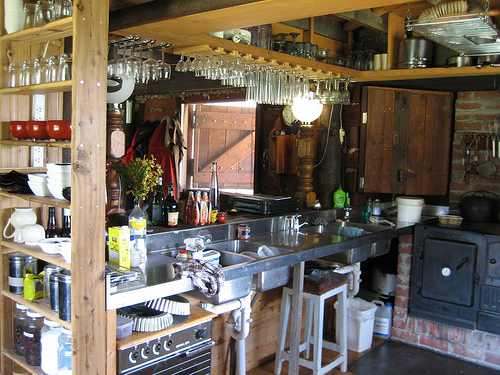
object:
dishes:
[44, 119, 73, 138]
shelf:
[0, 138, 72, 147]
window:
[184, 98, 257, 196]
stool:
[273, 271, 351, 374]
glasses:
[158, 41, 174, 79]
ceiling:
[108, 0, 407, 52]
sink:
[327, 220, 394, 234]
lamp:
[290, 98, 325, 209]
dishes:
[26, 180, 54, 197]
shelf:
[0, 189, 71, 209]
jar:
[20, 309, 45, 365]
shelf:
[1, 348, 42, 375]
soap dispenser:
[363, 196, 372, 224]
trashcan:
[333, 296, 378, 353]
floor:
[252, 321, 499, 374]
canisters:
[7, 250, 39, 295]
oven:
[405, 222, 499, 335]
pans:
[140, 293, 191, 316]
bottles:
[160, 182, 182, 228]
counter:
[129, 198, 147, 233]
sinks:
[207, 238, 302, 257]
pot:
[457, 189, 499, 219]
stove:
[405, 222, 499, 336]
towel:
[166, 257, 228, 298]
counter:
[106, 215, 436, 311]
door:
[192, 103, 256, 188]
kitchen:
[1, 0, 500, 374]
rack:
[106, 33, 174, 53]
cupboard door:
[361, 85, 454, 196]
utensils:
[458, 131, 478, 186]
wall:
[448, 91, 499, 208]